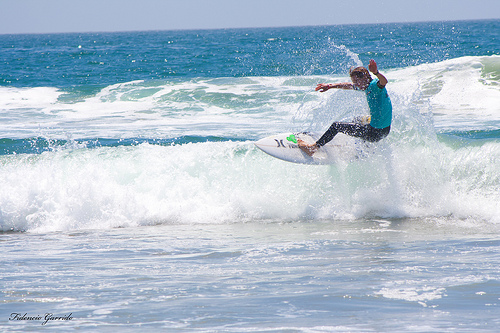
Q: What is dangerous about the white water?
A: There may be a current underneath from the wave break.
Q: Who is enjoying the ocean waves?
A: The surfer.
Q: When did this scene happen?
A: Noon.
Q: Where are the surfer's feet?
A: On the surfboard.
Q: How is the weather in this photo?
A: Sunny and hot.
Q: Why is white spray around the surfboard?
A: The surfer is moving fast.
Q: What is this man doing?
A: Surfing.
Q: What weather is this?
A: Sunny and clear.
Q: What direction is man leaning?
A: Backward.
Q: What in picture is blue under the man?
A: Water.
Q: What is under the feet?
A: Surfboard.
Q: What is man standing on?
A: Surfboard.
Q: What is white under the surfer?
A: Surfboard.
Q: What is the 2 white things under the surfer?
A: Board and wave.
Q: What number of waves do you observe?
A: 2.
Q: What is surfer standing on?
A: Surfboard.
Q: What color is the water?
A: The water is blue.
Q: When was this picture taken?
A: It was taken in the day time.